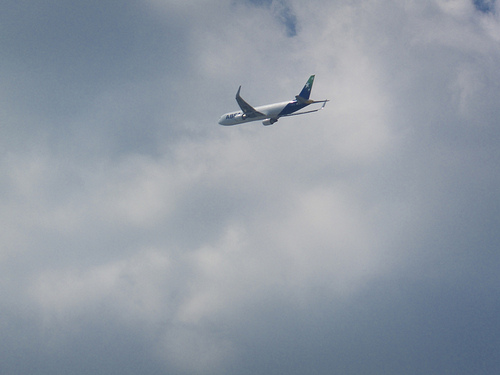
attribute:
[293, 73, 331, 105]
tail — dark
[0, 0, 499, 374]
clouds — white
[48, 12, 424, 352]
clouds — white 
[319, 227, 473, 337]
cloud — dark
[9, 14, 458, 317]
sky — blue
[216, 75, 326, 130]
plane — one, above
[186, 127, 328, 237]
clouds — white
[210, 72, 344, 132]
plane — white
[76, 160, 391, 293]
clouds — white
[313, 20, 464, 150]
clouds — white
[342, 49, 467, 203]
clouds — white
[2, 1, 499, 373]
sky — cloudy, blue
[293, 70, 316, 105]
tail — blue 